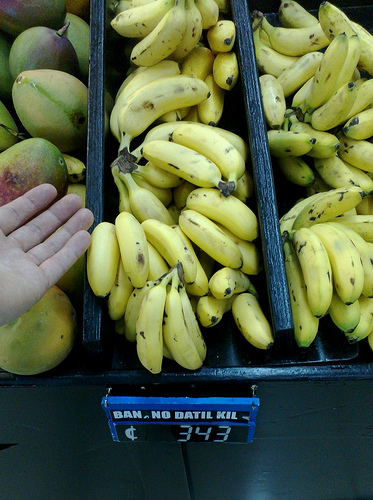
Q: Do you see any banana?
A: Yes, there is a banana.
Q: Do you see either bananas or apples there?
A: Yes, there is a banana.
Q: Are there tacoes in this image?
A: No, there are no tacoes.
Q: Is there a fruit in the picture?
A: Yes, there is a fruit.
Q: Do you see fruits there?
A: Yes, there is a fruit.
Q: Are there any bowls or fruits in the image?
A: Yes, there is a fruit.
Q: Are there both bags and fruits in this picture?
A: No, there is a fruit but no bags.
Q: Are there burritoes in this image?
A: No, there are no burritoes.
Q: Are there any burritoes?
A: No, there are no burritoes.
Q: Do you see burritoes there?
A: No, there are no burritoes.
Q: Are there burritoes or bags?
A: No, there are no burritoes or bags.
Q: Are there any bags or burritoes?
A: No, there are no burritoes or bags.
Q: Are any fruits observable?
A: Yes, there is a fruit.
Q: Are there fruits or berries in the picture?
A: Yes, there is a fruit.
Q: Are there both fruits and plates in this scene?
A: No, there is a fruit but no plates.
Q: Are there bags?
A: No, there are no bags.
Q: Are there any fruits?
A: Yes, there is a fruit.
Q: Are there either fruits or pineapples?
A: Yes, there is a fruit.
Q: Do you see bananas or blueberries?
A: Yes, there is a banana.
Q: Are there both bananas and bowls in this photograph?
A: No, there is a banana but no bowls.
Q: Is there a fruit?
A: Yes, there is a fruit.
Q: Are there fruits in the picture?
A: Yes, there is a fruit.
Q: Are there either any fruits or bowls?
A: Yes, there is a fruit.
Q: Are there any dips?
A: No, there are no dips.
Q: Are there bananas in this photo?
A: Yes, there is a banana.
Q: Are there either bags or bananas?
A: Yes, there is a banana.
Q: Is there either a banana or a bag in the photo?
A: Yes, there is a banana.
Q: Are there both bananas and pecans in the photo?
A: No, there is a banana but no pecans.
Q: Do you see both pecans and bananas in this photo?
A: No, there is a banana but no pecans.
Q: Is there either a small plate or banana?
A: Yes, there is a small banana.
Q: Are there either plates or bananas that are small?
A: Yes, the banana is small.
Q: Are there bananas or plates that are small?
A: Yes, the banana is small.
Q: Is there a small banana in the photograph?
A: Yes, there is a small banana.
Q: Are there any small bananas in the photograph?
A: Yes, there is a small banana.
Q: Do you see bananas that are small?
A: Yes, there is a banana that is small.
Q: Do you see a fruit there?
A: Yes, there is a fruit.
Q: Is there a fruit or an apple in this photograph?
A: Yes, there is a fruit.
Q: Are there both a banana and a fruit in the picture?
A: Yes, there are both a fruit and a banana.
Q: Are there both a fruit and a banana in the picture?
A: Yes, there are both a fruit and a banana.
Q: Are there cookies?
A: No, there are no cookies.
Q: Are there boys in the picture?
A: No, there are no boys.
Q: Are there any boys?
A: No, there are no boys.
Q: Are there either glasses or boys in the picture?
A: No, there are no boys or glasses.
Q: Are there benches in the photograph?
A: No, there are no benches.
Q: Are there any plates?
A: No, there are no plates.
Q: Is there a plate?
A: No, there are no plates.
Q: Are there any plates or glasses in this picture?
A: No, there are no plates or glasses.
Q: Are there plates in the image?
A: No, there are no plates.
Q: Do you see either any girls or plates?
A: No, there are no plates or girls.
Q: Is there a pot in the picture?
A: No, there are no pots.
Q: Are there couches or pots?
A: No, there are no pots or couches.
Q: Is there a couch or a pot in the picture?
A: No, there are no pots or couches.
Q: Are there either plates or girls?
A: No, there are no plates or girls.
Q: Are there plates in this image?
A: No, there are no plates.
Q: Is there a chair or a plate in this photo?
A: No, there are no plates or chairs.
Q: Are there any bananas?
A: Yes, there is a banana.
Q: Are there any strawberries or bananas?
A: Yes, there is a banana.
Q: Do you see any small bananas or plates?
A: Yes, there is a small banana.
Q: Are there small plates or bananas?
A: Yes, there is a small banana.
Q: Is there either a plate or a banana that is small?
A: Yes, the banana is small.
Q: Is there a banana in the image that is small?
A: Yes, there is a small banana.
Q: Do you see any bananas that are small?
A: Yes, there is a banana that is small.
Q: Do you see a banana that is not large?
A: Yes, there is a small banana.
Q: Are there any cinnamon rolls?
A: No, there are no cinnamon rolls.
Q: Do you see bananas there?
A: Yes, there is a banana.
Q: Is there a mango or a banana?
A: Yes, there is a banana.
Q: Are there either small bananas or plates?
A: Yes, there is a small banana.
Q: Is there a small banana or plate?
A: Yes, there is a small banana.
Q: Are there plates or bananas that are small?
A: Yes, the banana is small.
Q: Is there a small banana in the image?
A: Yes, there is a small banana.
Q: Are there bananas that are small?
A: Yes, there is a banana that is small.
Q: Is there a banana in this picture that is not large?
A: Yes, there is a small banana.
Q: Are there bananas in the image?
A: Yes, there is a banana.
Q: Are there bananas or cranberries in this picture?
A: Yes, there is a banana.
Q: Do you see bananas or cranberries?
A: Yes, there is a banana.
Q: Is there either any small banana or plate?
A: Yes, there is a small banana.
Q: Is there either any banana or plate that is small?
A: Yes, the banana is small.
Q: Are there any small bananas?
A: Yes, there is a small banana.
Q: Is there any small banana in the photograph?
A: Yes, there is a small banana.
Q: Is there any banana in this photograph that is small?
A: Yes, there is a banana that is small.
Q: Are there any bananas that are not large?
A: Yes, there is a small banana.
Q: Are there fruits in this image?
A: Yes, there is a fruit.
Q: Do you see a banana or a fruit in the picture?
A: Yes, there is a fruit.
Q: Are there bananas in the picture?
A: Yes, there is a banana.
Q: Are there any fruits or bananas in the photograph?
A: Yes, there is a banana.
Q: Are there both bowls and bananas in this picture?
A: No, there is a banana but no bowls.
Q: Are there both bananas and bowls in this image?
A: No, there is a banana but no bowls.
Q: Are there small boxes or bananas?
A: Yes, there is a small banana.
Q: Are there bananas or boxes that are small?
A: Yes, the banana is small.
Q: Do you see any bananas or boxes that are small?
A: Yes, the banana is small.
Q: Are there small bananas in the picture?
A: Yes, there is a small banana.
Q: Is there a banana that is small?
A: Yes, there is a banana that is small.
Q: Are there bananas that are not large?
A: Yes, there is a small banana.